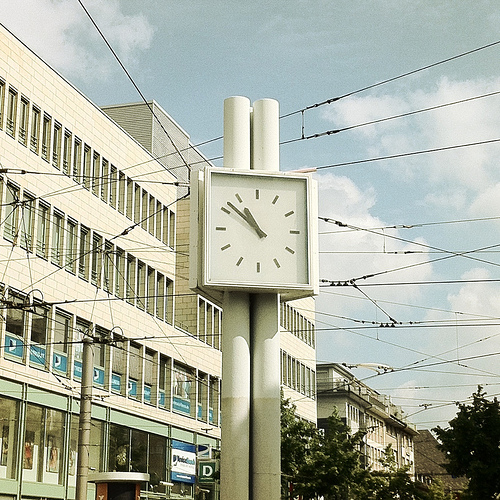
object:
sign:
[171, 440, 196, 484]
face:
[210, 172, 308, 284]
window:
[131, 427, 147, 473]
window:
[149, 432, 167, 493]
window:
[108, 421, 130, 474]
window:
[86, 417, 104, 470]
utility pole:
[76, 338, 94, 499]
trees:
[281, 383, 500, 500]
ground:
[424, 157, 454, 206]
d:
[203, 465, 214, 476]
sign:
[199, 462, 216, 484]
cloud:
[435, 270, 500, 363]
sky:
[0, 1, 500, 431]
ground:
[229, 77, 289, 118]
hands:
[226, 201, 268, 239]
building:
[0, 20, 318, 500]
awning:
[85, 471, 149, 483]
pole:
[205, 166, 314, 292]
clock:
[200, 166, 313, 290]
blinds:
[0, 77, 175, 251]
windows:
[64, 216, 76, 277]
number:
[215, 189, 300, 272]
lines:
[0, 60, 500, 428]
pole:
[219, 293, 279, 500]